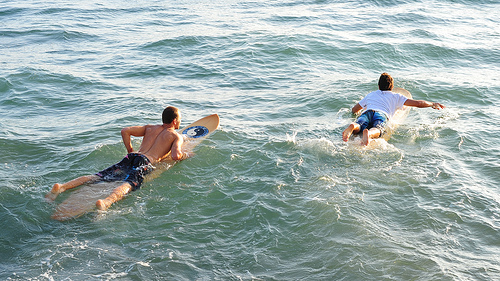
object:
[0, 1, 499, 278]
water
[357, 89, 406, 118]
t-shirt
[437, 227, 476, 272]
side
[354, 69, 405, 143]
man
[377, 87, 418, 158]
surfboard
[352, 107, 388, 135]
trunks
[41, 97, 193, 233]
man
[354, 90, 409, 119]
white shirt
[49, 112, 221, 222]
surfboard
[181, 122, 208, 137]
logo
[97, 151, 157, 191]
swim trunks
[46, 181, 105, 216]
feet